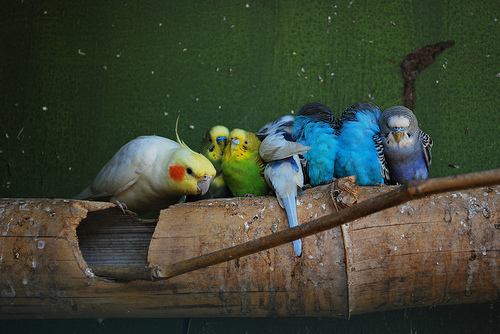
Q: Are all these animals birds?
A: Yes, all the animals are birds.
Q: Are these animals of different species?
A: No, all the animals are birds.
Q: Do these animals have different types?
A: No, all the animals are birds.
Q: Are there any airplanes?
A: No, there are no airplanes.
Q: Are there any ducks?
A: No, there are no ducks.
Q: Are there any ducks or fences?
A: No, there are no ducks or fences.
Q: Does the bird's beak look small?
A: Yes, the beak is small.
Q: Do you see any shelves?
A: No, there are no shelves.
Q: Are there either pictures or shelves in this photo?
A: No, there are no shelves or pictures.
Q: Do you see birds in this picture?
A: Yes, there is a bird.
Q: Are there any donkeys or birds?
A: Yes, there is a bird.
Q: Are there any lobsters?
A: No, there are no lobsters.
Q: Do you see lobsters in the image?
A: No, there are no lobsters.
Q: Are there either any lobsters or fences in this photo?
A: No, there are no lobsters or fences.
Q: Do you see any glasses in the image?
A: No, there are no glasses.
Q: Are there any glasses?
A: No, there are no glasses.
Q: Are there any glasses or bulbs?
A: No, there are no glasses or bulbs.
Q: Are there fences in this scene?
A: No, there are no fences.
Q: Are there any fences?
A: No, there are no fences.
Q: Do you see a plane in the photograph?
A: No, there are no airplanes.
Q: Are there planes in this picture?
A: No, there are no planes.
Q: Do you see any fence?
A: No, there are no fences.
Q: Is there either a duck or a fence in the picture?
A: No, there are no fences or ducks.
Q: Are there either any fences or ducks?
A: No, there are no fences or ducks.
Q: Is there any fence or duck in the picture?
A: No, there are no fences or ducks.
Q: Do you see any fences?
A: No, there are no fences.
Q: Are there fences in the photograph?
A: No, there are no fences.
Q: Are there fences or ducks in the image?
A: No, there are no fences or ducks.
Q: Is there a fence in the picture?
A: No, there are no fences.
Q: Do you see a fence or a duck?
A: No, there are no fences or ducks.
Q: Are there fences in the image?
A: No, there are no fences.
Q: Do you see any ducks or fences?
A: No, there are no fences or ducks.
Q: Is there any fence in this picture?
A: No, there are no fences.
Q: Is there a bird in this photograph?
A: Yes, there are birds.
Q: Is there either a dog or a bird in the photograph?
A: Yes, there are birds.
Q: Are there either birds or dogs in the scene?
A: Yes, there are birds.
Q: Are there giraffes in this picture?
A: No, there are no giraffes.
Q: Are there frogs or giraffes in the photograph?
A: No, there are no giraffes or frogs.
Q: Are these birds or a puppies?
A: These are birds.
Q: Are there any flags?
A: No, there are no flags.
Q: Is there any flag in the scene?
A: No, there are no flags.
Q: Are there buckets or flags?
A: No, there are no flags or buckets.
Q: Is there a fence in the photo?
A: No, there are no fences.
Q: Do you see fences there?
A: No, there are no fences.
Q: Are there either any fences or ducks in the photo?
A: No, there are no fences or ducks.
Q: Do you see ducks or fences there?
A: No, there are no fences or ducks.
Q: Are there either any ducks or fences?
A: No, there are no fences or ducks.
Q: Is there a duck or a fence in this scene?
A: No, there are no fences or ducks.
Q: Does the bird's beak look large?
A: No, the beak is small.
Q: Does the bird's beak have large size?
A: No, the beak is small.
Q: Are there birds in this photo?
A: Yes, there is a bird.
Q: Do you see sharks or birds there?
A: Yes, there is a bird.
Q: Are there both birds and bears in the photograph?
A: No, there is a bird but no bears.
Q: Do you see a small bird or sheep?
A: Yes, there is a small bird.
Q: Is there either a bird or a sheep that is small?
A: Yes, the bird is small.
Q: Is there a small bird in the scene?
A: Yes, there is a small bird.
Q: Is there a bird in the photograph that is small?
A: Yes, there is a bird that is small.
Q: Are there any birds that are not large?
A: Yes, there is a small bird.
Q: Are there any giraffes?
A: No, there are no giraffes.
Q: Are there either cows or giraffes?
A: No, there are no giraffes or cows.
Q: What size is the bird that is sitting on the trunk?
A: The bird is small.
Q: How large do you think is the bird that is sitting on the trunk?
A: The bird is small.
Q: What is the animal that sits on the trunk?
A: The animal is a bird.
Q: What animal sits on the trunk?
A: The animal is a bird.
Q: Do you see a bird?
A: Yes, there is a bird.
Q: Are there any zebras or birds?
A: Yes, there is a bird.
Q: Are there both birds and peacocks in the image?
A: No, there is a bird but no peacocks.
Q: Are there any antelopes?
A: No, there are no antelopes.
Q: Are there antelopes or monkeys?
A: No, there are no antelopes or monkeys.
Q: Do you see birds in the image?
A: Yes, there is a bird.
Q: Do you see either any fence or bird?
A: Yes, there is a bird.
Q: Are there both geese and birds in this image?
A: No, there is a bird but no geese.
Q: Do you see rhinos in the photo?
A: No, there are no rhinos.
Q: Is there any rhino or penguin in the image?
A: No, there are no rhinos or penguins.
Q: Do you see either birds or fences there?
A: Yes, there is a bird.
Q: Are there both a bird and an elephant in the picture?
A: No, there is a bird but no elephants.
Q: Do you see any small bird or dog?
A: Yes, there is a small bird.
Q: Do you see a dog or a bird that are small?
A: Yes, the bird is small.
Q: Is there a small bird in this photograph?
A: Yes, there is a small bird.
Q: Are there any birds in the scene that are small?
A: Yes, there is a bird that is small.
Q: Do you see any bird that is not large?
A: Yes, there is a small bird.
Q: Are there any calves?
A: No, there are no calves.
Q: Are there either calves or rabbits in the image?
A: No, there are no calves or rabbits.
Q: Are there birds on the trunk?
A: Yes, there is a bird on the trunk.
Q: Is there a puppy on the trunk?
A: No, there is a bird on the trunk.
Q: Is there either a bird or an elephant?
A: Yes, there is a bird.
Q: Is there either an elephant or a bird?
A: Yes, there is a bird.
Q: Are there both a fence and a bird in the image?
A: No, there is a bird but no fences.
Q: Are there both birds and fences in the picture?
A: No, there is a bird but no fences.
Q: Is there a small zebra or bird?
A: Yes, there is a small bird.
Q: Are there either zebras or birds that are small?
A: Yes, the bird is small.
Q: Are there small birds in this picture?
A: Yes, there is a small bird.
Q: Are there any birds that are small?
A: Yes, there is a small bird.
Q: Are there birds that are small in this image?
A: Yes, there is a small bird.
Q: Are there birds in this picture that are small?
A: Yes, there is a bird that is small.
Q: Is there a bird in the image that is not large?
A: Yes, there is a small bird.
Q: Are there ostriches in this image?
A: No, there are no ostriches.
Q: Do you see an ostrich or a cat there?
A: No, there are no ostriches or cats.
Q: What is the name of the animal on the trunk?
A: The animal is a bird.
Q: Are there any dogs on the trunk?
A: No, there is a bird on the trunk.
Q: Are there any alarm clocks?
A: No, there are no alarm clocks.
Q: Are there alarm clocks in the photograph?
A: No, there are no alarm clocks.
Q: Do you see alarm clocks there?
A: No, there are no alarm clocks.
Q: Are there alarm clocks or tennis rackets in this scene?
A: No, there are no alarm clocks or tennis rackets.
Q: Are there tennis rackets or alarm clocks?
A: No, there are no alarm clocks or tennis rackets.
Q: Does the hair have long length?
A: Yes, the hair is long.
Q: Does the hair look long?
A: Yes, the hair is long.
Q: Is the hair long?
A: Yes, the hair is long.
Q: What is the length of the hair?
A: The hair is long.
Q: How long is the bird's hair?
A: The hair is long.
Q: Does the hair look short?
A: No, the hair is long.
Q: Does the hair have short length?
A: No, the hair is long.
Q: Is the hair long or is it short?
A: The hair is long.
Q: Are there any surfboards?
A: No, there are no surfboards.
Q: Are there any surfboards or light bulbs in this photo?
A: No, there are no surfboards or light bulbs.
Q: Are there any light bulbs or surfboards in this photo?
A: No, there are no surfboards or light bulbs.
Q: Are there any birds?
A: Yes, there is a bird.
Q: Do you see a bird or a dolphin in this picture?
A: Yes, there is a bird.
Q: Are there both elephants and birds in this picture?
A: No, there is a bird but no elephants.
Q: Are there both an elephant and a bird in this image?
A: No, there is a bird but no elephants.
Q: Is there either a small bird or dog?
A: Yes, there is a small bird.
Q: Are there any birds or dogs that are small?
A: Yes, the bird is small.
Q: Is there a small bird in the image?
A: Yes, there is a small bird.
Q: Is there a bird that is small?
A: Yes, there is a bird that is small.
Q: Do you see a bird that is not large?
A: Yes, there is a small bird.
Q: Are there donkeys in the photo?
A: No, there are no donkeys.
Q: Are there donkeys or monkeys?
A: No, there are no donkeys or monkeys.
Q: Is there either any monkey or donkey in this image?
A: No, there are no donkeys or monkeys.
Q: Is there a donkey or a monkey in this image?
A: No, there are no donkeys or monkeys.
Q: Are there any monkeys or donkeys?
A: No, there are no donkeys or monkeys.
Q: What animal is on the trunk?
A: The bird is on the trunk.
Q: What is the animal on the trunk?
A: The animal is a bird.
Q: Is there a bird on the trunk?
A: Yes, there is a bird on the trunk.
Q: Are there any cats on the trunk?
A: No, there is a bird on the trunk.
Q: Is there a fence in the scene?
A: No, there are no fences.